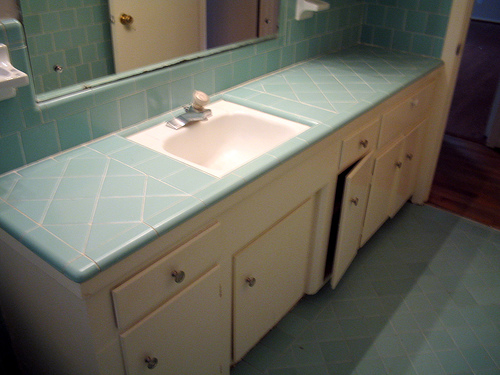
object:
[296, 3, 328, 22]
holder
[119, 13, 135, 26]
doorknob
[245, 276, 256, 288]
knob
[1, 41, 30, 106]
holder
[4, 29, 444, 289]
counter top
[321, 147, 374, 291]
cabinet door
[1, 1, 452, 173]
tile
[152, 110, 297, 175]
bathroom sink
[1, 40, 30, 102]
soap holder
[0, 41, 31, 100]
toothbrush holder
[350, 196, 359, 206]
knob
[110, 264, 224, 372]
cabinet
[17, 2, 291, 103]
bathroom mirror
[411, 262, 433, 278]
tile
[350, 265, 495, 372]
floor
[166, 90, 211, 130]
faucet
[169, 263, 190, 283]
knob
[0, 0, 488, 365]
bathroom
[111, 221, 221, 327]
drawer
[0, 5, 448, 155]
wall